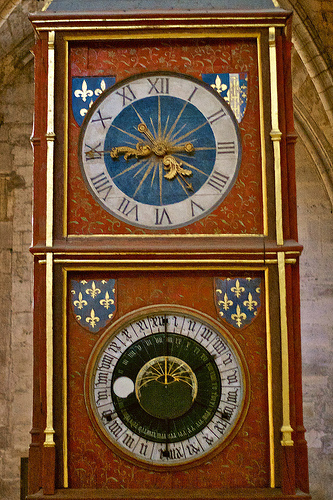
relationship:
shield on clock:
[197, 68, 253, 116] [77, 64, 249, 229]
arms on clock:
[72, 76, 104, 109] [86, 304, 257, 471]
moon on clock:
[111, 374, 134, 397] [86, 304, 257, 471]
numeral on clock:
[207, 101, 231, 139] [132, 107, 241, 197]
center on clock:
[114, 339, 194, 426] [83, 71, 231, 236]